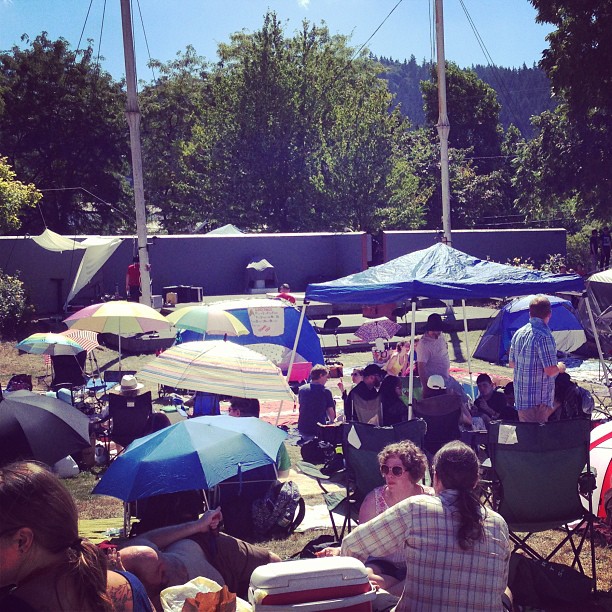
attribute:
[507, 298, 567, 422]
man — standing, human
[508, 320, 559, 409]
shirt — blue, white, plaid, short sleeved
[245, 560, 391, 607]
cooler — red, white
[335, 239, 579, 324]
canopy — blue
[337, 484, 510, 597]
plaid shirt — plaid 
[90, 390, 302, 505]
blue umbrella — blue 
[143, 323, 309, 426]
striped umbrella — striped 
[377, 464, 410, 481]
black sunglasses — Black 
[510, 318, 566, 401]
plaid shirt — plaid 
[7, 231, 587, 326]
blue fence — blue 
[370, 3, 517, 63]
sky — blue , clear 